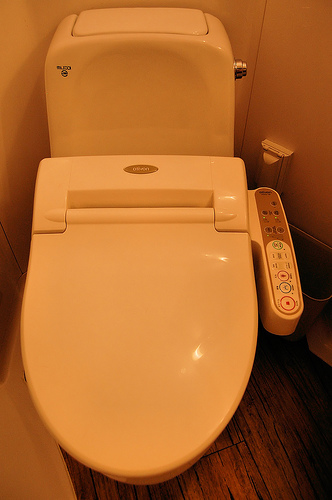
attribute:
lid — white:
[22, 204, 261, 463]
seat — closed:
[16, 149, 259, 490]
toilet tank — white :
[43, 6, 236, 156]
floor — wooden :
[58, 314, 330, 499]